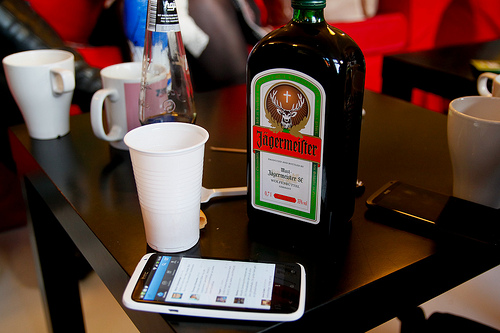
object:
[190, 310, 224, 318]
white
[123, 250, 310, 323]
phone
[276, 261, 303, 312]
back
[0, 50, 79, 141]
cup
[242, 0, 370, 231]
glass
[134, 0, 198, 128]
bottle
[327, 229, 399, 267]
brown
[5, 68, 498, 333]
table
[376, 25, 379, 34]
red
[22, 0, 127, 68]
couch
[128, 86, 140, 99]
pink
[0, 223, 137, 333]
floor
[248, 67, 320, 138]
green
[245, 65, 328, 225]
label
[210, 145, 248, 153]
stick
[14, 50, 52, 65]
coffee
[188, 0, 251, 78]
person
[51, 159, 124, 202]
reflection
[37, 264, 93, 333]
legs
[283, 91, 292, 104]
cross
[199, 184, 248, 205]
spoon